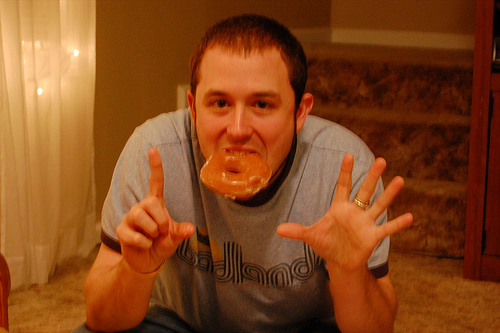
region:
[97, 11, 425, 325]
man with doughnut in mouth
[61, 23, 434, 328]
man holding up six finger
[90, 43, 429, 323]
man with grey shirt on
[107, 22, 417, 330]
man wearing ring on finger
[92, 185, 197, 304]
rubber band on wrist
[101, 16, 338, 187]
dark short hair of man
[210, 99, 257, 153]
nose of man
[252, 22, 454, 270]
brown steps beind man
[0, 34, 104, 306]
white curtain by man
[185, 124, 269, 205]
brown doughnut in mouth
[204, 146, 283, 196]
a krispy kreme donut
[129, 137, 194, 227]
the guy saying he is number 1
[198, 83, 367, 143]
the eyes of the man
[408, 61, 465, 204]
stairs leading up stairs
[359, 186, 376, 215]
the mans wedding band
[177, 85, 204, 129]
the ear of the man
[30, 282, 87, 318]
the carpet on the ground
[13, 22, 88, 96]
a lamp behind the curtain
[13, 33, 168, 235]
white curtains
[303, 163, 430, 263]
the man holding 5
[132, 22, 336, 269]
man is bitting donut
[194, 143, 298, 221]
the donut is brown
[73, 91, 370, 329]
man is wearing shirt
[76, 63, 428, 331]
the shirt is gray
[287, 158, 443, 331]
man is wearing a ring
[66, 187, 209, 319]
man is wearing a baller band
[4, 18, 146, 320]
the curtain is white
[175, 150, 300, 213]
the donut has frosting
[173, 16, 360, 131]
the hair is brown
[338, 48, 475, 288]
the stairs is brown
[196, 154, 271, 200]
a glazed doughnut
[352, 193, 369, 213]
a male wedding ring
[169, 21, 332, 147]
a man with brown hair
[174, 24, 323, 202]
a man with a doughnut in his mouth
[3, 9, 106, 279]
white window drapes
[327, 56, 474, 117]
brown carpet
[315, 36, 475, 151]
stairs with brown carpet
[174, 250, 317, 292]
logo on shirt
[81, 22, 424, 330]
man in a grey shirt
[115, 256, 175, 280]
a yellow watch band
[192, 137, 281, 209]
A glazed dough nut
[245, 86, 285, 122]
A mans left eye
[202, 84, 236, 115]
A mans right eye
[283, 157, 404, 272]
A mans left hand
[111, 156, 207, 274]
A mans right hand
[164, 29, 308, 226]
A man eating a dough nut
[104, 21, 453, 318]
A man holding his hands up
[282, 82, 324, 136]
A mans left ear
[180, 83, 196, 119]
A mans right ear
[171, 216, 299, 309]
A grey mens shirt